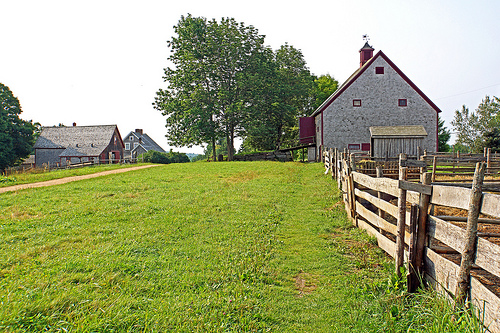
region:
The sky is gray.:
[0, 0, 495, 155]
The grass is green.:
[1, 162, 482, 330]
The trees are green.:
[1, 16, 498, 158]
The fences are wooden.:
[317, 140, 499, 327]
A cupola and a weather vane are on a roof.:
[312, 30, 442, 155]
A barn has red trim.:
[305, 30, 440, 157]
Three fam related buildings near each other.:
[16, 30, 432, 172]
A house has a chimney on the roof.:
[123, 126, 174, 158]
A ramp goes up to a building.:
[230, 115, 318, 160]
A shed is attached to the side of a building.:
[310, 35, 441, 167]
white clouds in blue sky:
[32, 31, 59, 53]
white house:
[307, 36, 427, 144]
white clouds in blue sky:
[448, 41, 480, 91]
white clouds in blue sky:
[401, 22, 455, 43]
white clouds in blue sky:
[94, 11, 121, 41]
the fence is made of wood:
[302, 132, 498, 310]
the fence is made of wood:
[311, 127, 488, 310]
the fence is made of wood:
[315, 151, 492, 308]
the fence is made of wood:
[350, 130, 450, 295]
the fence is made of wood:
[310, 139, 462, 308]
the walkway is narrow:
[17, 160, 75, 201]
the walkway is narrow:
[2, 170, 87, 212]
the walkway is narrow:
[2, 162, 72, 202]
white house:
[327, 31, 427, 126]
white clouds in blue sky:
[427, 0, 479, 35]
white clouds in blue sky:
[405, 35, 457, 63]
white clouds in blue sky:
[284, 3, 354, 38]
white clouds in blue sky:
[15, 41, 47, 59]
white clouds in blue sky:
[57, 59, 94, 104]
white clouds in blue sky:
[45, 36, 110, 87]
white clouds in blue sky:
[7, 26, 82, 67]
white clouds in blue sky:
[51, 43, 108, 71]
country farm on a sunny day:
[7, 3, 498, 283]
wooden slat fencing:
[331, 151, 498, 296]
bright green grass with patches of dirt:
[142, 166, 316, 331]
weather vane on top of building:
[357, 32, 374, 64]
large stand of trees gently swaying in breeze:
[162, 5, 315, 165]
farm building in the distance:
[35, 123, 125, 173]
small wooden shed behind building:
[369, 120, 426, 163]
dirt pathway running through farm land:
[10, 173, 97, 198]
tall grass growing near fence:
[405, 274, 464, 331]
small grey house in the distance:
[118, 127, 153, 162]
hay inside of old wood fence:
[322, 144, 499, 331]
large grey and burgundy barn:
[300, 35, 443, 162]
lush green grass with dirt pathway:
[0, 160, 491, 331]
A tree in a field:
[173, 10, 256, 167]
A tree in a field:
[231, 34, 296, 159]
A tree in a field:
[195, 61, 233, 152]